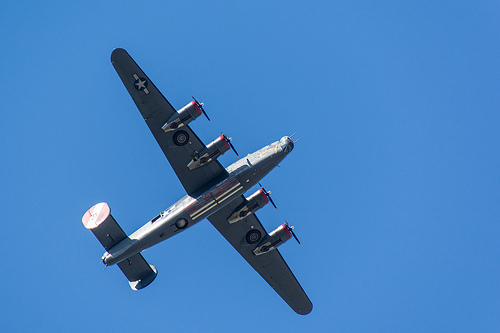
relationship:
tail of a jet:
[79, 202, 157, 292] [82, 46, 314, 316]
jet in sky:
[82, 46, 314, 316] [9, 11, 484, 312]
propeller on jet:
[192, 95, 209, 124] [82, 46, 314, 314]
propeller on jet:
[220, 132, 239, 157] [82, 46, 314, 314]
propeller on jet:
[257, 182, 277, 209] [82, 46, 314, 314]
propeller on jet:
[284, 218, 300, 245] [82, 46, 314, 314]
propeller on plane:
[284, 219, 301, 245] [80, 41, 347, 306]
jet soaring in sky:
[82, 46, 314, 314] [1, 1, 494, 330]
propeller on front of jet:
[191, 95, 211, 122] [82, 46, 314, 316]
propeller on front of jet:
[177, 94, 301, 245] [82, 46, 314, 316]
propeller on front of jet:
[257, 182, 277, 210] [82, 46, 314, 316]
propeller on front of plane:
[284, 219, 301, 245] [67, 33, 346, 325]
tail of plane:
[81, 202, 158, 290] [81, 46, 315, 324]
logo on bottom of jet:
[176, 179, 234, 271] [82, 46, 314, 316]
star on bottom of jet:
[135, 79, 147, 90] [82, 46, 314, 316]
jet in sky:
[82, 46, 314, 316] [1, 1, 494, 330]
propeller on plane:
[191, 95, 211, 122] [67, 33, 346, 325]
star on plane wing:
[130, 75, 148, 89] [110, 47, 225, 195]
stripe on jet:
[184, 181, 238, 217] [82, 46, 314, 316]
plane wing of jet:
[110, 47, 230, 195] [82, 46, 314, 316]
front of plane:
[270, 131, 298, 158] [85, 36, 387, 311]